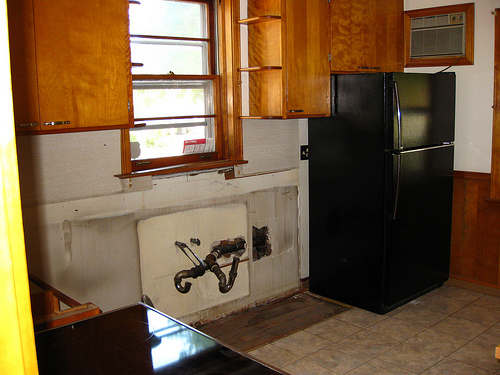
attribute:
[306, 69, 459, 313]
refrigerator — black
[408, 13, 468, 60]
a.c. unit — framed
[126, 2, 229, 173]
window — brown, showing daylight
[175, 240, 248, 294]
pipes — exposed, for sink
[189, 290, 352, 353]
patch — untiled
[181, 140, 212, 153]
sign — white, red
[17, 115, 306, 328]
wall — tore up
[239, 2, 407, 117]
cabinets — brown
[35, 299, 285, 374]
counter — black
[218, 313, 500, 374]
floor — tiled